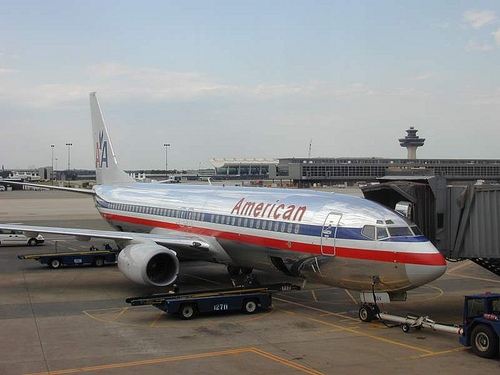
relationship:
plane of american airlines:
[4, 85, 456, 318] [84, 127, 121, 180]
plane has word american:
[4, 85, 456, 318] [223, 191, 316, 231]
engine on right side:
[106, 239, 188, 294] [5, 211, 222, 305]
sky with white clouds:
[3, 0, 499, 177] [13, 59, 474, 126]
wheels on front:
[354, 295, 388, 330] [337, 252, 447, 344]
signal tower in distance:
[393, 120, 432, 164] [288, 107, 497, 163]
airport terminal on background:
[202, 155, 500, 184] [15, 125, 500, 182]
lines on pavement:
[17, 303, 433, 373] [1, 278, 494, 372]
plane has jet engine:
[4, 85, 456, 318] [106, 239, 188, 294]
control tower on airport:
[393, 120, 432, 164] [202, 155, 500, 184]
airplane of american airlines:
[4, 85, 456, 318] [84, 127, 121, 180]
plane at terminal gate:
[4, 85, 456, 318] [174, 147, 499, 200]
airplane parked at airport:
[4, 85, 456, 318] [0, 194, 499, 371]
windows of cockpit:
[355, 214, 430, 247] [354, 204, 447, 271]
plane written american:
[4, 85, 456, 318] [223, 191, 316, 231]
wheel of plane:
[354, 295, 388, 330] [4, 85, 456, 318]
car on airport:
[4, 228, 46, 247] [0, 194, 499, 371]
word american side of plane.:
[223, 191, 316, 231] [100, 190, 345, 250]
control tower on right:
[393, 120, 432, 164] [397, 52, 493, 374]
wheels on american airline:
[354, 295, 388, 330] [89, 132, 116, 173]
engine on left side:
[106, 239, 188, 294] [70, 198, 344, 311]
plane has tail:
[4, 85, 456, 318] [6, 85, 169, 195]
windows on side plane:
[106, 203, 303, 239] [4, 85, 456, 318]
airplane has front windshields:
[4, 85, 456, 318] [355, 214, 430, 247]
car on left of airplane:
[4, 228, 46, 247] [4, 85, 456, 318]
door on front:
[312, 205, 343, 261] [326, 196, 458, 334]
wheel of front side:
[27, 236, 38, 250] [23, 234, 47, 246]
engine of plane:
[106, 239, 188, 294] [4, 85, 456, 318]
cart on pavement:
[121, 280, 299, 319] [0, 240, 499, 373]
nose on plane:
[366, 213, 453, 303] [4, 85, 456, 318]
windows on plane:
[106, 203, 303, 239] [4, 85, 456, 318]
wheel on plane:
[354, 295, 388, 330] [4, 85, 456, 318]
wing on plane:
[4, 219, 202, 253] [4, 85, 456, 318]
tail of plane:
[6, 85, 169, 195] [4, 85, 456, 318]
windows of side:
[106, 203, 303, 239] [100, 190, 345, 250]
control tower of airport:
[393, 120, 432, 164] [0, 194, 499, 371]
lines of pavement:
[17, 303, 433, 373] [0, 240, 499, 373]